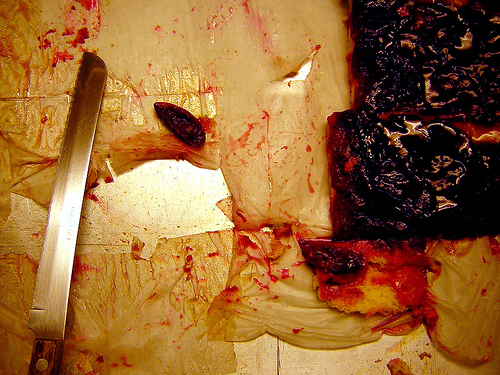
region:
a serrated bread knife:
[21, 50, 113, 372]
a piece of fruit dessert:
[304, 237, 428, 317]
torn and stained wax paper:
[12, 2, 351, 367]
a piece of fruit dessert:
[323, 109, 498, 239]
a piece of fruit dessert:
[343, 0, 499, 112]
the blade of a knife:
[25, 43, 110, 331]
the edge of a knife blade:
[21, 50, 90, 307]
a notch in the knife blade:
[27, 300, 49, 317]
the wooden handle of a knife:
[26, 324, 66, 374]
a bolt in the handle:
[32, 352, 54, 373]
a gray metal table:
[1, 153, 231, 267]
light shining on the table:
[143, 159, 233, 225]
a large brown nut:
[146, 93, 213, 153]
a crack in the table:
[268, 326, 291, 373]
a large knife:
[20, 46, 117, 373]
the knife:
[30, 74, 224, 331]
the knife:
[28, 48, 123, 267]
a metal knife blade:
[24, 47, 114, 337]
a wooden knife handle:
[21, 332, 68, 373]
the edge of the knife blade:
[23, 48, 87, 330]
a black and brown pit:
[149, 98, 216, 153]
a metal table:
[0, 150, 231, 257]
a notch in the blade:
[26, 300, 51, 314]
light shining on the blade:
[42, 166, 96, 248]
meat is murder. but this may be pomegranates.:
[0, 1, 499, 374]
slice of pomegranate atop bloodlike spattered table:
[148, 97, 210, 152]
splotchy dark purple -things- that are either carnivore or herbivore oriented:
[295, 0, 498, 280]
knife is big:
[15, 40, 111, 374]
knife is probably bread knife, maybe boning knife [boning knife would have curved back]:
[8, 40, 108, 370]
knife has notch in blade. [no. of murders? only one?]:
[24, 304, 49, 318]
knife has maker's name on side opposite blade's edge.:
[63, 193, 79, 245]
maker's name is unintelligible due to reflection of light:
[57, 161, 94, 281]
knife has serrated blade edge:
[28, 46, 85, 327]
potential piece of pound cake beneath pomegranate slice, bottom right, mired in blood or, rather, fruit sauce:
[306, 237, 427, 328]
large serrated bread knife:
[13, 37, 111, 369]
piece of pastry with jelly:
[299, 240, 433, 329]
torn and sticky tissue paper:
[183, 273, 293, 365]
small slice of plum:
[149, 91, 224, 153]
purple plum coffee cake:
[323, 107, 430, 242]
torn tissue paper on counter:
[267, 36, 332, 100]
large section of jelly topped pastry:
[308, 11, 492, 241]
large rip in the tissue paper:
[12, 166, 256, 258]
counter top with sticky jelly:
[106, 173, 236, 253]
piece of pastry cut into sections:
[319, 26, 399, 173]